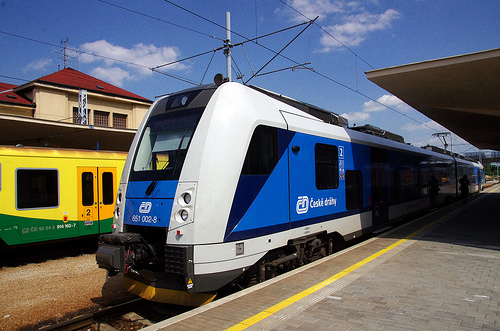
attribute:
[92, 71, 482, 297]
train — blue, white, arriving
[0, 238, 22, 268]
wheels — black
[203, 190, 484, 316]
platform — train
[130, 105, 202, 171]
windshield — train's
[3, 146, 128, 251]
passenger car — yellow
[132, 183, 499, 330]
platform — train, concrete, brick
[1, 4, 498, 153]
sky — blue, clear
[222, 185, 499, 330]
line — yellow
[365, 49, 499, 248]
overhead shelter — passenger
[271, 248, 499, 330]
bricks — gray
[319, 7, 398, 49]
cloud — small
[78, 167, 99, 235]
door — orange, yellow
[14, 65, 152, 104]
roof — red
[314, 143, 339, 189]
window — dark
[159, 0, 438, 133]
wire — hanging, above the train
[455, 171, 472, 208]
person — walking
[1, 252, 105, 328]
dirt — brown